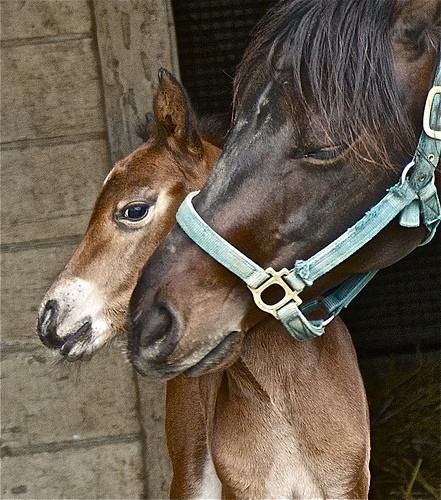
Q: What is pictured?
A: Two horses.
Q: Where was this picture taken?
A: A horse stall.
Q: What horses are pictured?
A: A brown mother with a tan foal.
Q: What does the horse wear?
A: A blue bridle.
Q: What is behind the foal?
A: The wooden wall of the horse stall.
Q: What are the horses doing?
A: Nuzzling.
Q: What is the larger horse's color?
A: Dark brown.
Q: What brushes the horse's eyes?
A: Here mane.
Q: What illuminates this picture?
A: Natural sunlight.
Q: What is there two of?
A: Horses.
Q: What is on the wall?
A: A board.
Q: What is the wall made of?
A: Wood.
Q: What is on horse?
A: Brown hair.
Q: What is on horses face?
A: Blue reigns.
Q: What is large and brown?
A: The horses.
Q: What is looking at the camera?
A: Baby horse.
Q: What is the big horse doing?
A: Nuzzling the baby horse.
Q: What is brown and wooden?
A: Wall.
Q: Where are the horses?
A: Next to each other.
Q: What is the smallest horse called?
A: Colt.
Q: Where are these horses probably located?
A: Stable.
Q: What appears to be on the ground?
A: Hay.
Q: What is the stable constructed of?
A: Wood.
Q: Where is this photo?
A: Barn.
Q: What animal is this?
A: Horse.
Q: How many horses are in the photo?
A: Two.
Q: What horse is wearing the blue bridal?
A: Mother.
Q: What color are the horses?
A: Brown.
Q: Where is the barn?
A: Farm.